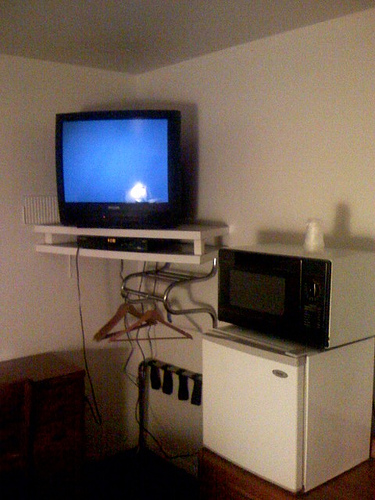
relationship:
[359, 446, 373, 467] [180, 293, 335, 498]
corner of refrigerator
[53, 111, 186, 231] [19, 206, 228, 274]
television on stand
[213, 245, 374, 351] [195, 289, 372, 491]
microwave on refrigerator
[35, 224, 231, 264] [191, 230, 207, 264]
shelf has corner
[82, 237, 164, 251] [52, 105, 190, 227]
dvd below television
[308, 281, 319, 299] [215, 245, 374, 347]
knob above microwave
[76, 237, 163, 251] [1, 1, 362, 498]
dvd in room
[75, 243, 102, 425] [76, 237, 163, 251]
cord to dvd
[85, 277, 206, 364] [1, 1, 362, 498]
hanger in room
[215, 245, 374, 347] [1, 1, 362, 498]
microwave in room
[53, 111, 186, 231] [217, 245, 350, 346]
television near microwave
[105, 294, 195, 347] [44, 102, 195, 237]
hanger under tv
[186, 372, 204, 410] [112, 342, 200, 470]
strap on chair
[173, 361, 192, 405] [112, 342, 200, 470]
strap on chair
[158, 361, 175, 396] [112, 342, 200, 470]
strap on chair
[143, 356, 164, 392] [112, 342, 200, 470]
strap on chair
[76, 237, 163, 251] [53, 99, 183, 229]
dvd under tv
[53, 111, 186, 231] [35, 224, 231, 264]
television on shelf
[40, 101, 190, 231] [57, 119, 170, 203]
television has screen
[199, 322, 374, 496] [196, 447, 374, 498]
mini fridge on table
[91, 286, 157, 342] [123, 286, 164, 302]
hanger on bar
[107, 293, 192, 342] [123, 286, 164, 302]
hanger on bar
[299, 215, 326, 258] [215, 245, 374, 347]
plastic cups on microwave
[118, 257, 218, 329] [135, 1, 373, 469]
bar mounted on wall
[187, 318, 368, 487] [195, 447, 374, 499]
refrigerator top on table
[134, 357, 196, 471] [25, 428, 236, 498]
bar with mat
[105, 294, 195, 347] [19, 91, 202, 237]
hanger below television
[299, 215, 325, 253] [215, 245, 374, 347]
plastic cups on microwave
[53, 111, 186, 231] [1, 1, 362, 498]
television in room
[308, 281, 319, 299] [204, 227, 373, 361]
knob on microwave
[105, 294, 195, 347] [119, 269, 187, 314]
hanger on rail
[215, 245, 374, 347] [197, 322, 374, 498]
microwave on mini fridge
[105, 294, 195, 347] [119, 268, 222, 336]
hanger on rack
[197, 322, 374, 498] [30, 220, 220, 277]
mini fridge sitting on a shelf